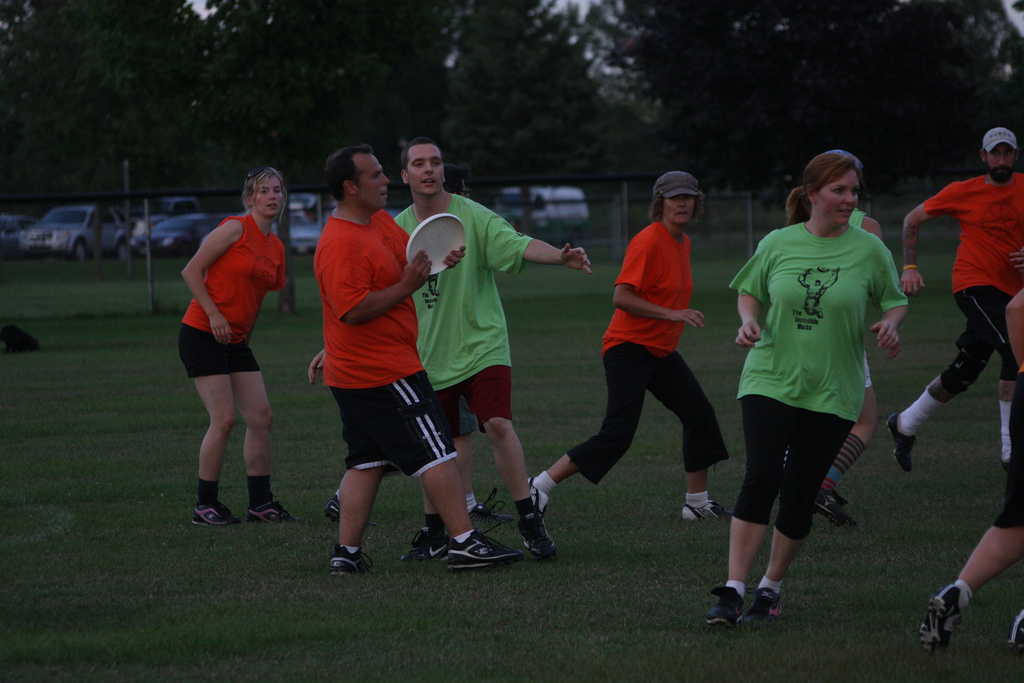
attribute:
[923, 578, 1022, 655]
shoes — black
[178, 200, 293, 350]
shirt — orange 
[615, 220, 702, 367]
shirt — orange 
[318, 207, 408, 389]
shirt — orange 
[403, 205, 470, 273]
frisbee — white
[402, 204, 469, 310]
frisbee — white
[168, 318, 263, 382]
shorts — black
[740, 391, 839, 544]
capris — black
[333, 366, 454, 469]
shorts — black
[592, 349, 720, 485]
pants — black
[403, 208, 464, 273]
frisbee — round, white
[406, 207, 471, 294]
man — Dark haired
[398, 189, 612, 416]
shirt — green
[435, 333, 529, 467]
shorts — red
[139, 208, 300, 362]
shirt — orange